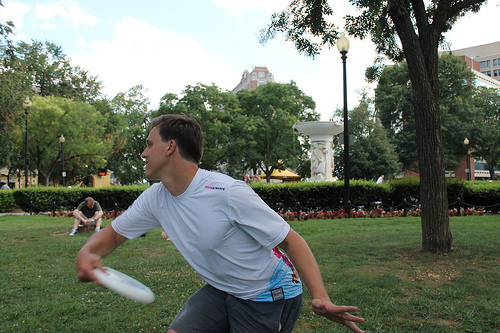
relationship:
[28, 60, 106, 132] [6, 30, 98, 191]
leaf on tree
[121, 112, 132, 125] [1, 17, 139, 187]
green leaf on tree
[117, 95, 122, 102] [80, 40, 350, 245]
leaf on tree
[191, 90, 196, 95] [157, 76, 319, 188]
leaf on tree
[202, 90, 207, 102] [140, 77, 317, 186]
leaf on tree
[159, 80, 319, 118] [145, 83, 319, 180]
green leaf on tree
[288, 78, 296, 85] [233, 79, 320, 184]
leaf on tree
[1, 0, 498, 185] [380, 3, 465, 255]
leaf on tree